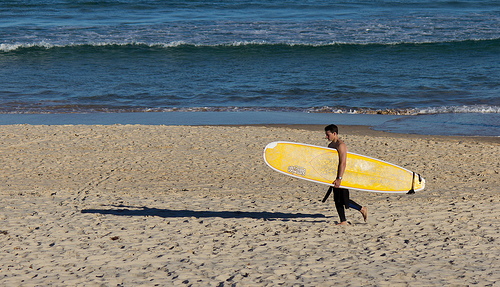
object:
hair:
[322, 123, 339, 133]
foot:
[330, 217, 351, 228]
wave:
[10, 25, 487, 63]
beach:
[1, 0, 498, 285]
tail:
[401, 168, 431, 196]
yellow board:
[265, 138, 475, 217]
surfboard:
[263, 139, 338, 186]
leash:
[405, 169, 422, 195]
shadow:
[81, 200, 335, 225]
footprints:
[395, 222, 499, 255]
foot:
[360, 205, 370, 224]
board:
[260, 141, 427, 195]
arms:
[335, 142, 346, 179]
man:
[323, 123, 369, 227]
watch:
[335, 175, 345, 180]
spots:
[280, 147, 408, 192]